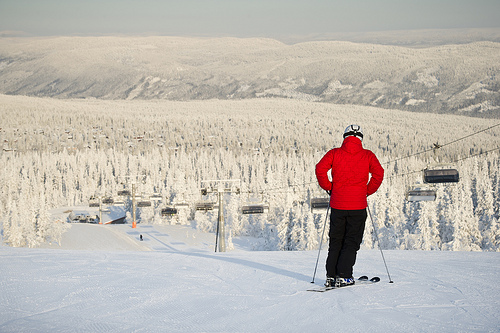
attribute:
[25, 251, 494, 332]
snow — fresh, white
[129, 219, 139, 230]
cone — orange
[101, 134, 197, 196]
trees — snow covered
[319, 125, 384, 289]
man — red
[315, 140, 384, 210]
jacket — red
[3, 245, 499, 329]
snow — white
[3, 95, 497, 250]
pine trees — snow covered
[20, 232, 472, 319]
ski slope — white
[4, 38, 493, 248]
landscape — snow covered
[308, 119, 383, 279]
man — ready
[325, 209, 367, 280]
pants — black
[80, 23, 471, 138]
mountain — frozen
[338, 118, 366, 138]
helmet — white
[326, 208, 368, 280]
snow pants — black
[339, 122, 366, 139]
helmet — white, ski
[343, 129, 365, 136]
band — black, goggle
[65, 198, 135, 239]
lodge — ski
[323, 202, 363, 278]
snow pants — black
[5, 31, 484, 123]
mountain — snow covered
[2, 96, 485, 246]
valley — snow covered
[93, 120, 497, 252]
lift — ski